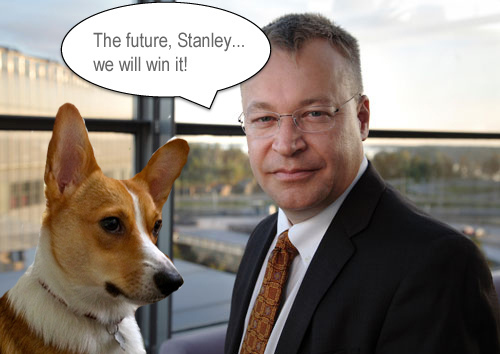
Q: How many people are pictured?
A: One.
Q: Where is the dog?
A: To the left.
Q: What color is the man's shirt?
A: White.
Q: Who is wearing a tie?
A: The man.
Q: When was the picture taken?
A: During daytime.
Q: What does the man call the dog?
A: Stanley.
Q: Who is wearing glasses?
A: The man.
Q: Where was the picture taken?
A: Office.